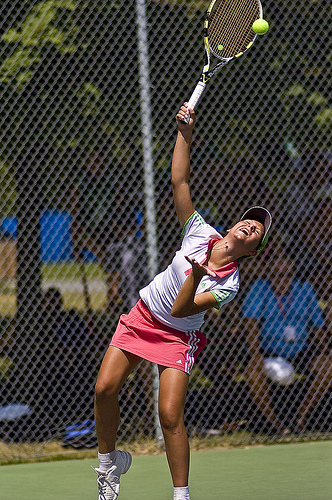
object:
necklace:
[212, 241, 231, 263]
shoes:
[173, 485, 190, 500]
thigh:
[95, 345, 143, 398]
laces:
[90, 465, 112, 497]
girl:
[89, 0, 272, 500]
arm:
[172, 129, 197, 229]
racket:
[177, 0, 263, 124]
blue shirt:
[241, 277, 324, 360]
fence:
[0, 0, 332, 465]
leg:
[158, 355, 191, 488]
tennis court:
[0, 441, 332, 500]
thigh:
[157, 364, 189, 428]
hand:
[176, 102, 196, 131]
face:
[233, 219, 263, 242]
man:
[241, 235, 332, 442]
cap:
[240, 206, 272, 261]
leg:
[94, 345, 142, 455]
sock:
[173, 485, 190, 500]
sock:
[97, 449, 116, 471]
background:
[0, 0, 331, 462]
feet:
[89, 450, 132, 499]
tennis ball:
[252, 18, 269, 34]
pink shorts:
[109, 299, 208, 376]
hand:
[184, 255, 216, 278]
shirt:
[139, 210, 240, 331]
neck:
[216, 233, 238, 263]